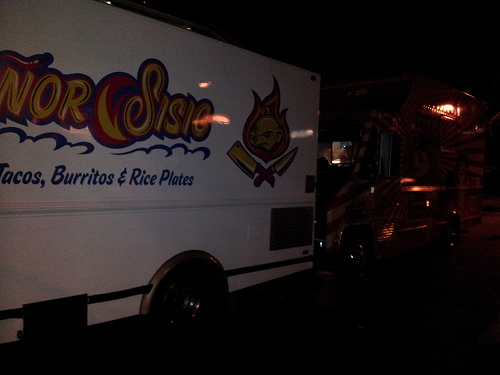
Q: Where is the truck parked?
A: The street.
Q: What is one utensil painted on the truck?
A: Cleaver.